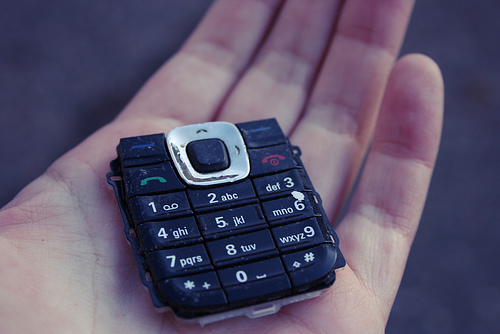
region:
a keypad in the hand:
[107, 102, 349, 323]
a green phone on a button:
[132, 164, 178, 190]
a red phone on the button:
[262, 153, 292, 168]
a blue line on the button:
[125, 133, 157, 151]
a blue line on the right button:
[248, 123, 278, 138]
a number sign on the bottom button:
[301, 249, 317, 264]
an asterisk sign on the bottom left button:
[184, 274, 196, 298]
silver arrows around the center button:
[163, 109, 253, 194]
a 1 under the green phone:
[135, 189, 185, 219]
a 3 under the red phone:
[281, 173, 301, 193]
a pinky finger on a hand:
[333, 52, 468, 279]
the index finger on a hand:
[99, 5, 281, 170]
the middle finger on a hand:
[216, 6, 354, 132]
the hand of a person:
[35, 15, 476, 289]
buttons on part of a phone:
[144, 156, 346, 279]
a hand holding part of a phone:
[70, 54, 487, 292]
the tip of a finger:
[373, 54, 472, 184]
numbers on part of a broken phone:
[145, 123, 368, 310]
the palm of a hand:
[56, 58, 446, 299]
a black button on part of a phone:
[183, 108, 255, 201]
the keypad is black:
[86, 103, 340, 314]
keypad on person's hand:
[61, 3, 402, 330]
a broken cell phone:
[106, 114, 352, 314]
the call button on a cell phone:
[127, 165, 180, 197]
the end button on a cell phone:
[250, 145, 290, 173]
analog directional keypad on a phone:
[163, 121, 251, 189]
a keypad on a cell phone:
[131, 173, 337, 290]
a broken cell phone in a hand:
[0, 0, 452, 329]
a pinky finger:
[336, 52, 451, 303]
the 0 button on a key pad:
[217, 253, 296, 285]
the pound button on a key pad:
[281, 246, 333, 274]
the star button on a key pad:
[176, 266, 220, 307]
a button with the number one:
[132, 198, 189, 215]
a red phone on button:
[249, 151, 291, 180]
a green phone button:
[130, 171, 189, 200]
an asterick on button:
[170, 265, 220, 306]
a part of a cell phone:
[38, 49, 467, 326]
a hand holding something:
[45, 24, 498, 308]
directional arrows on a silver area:
[152, 117, 257, 183]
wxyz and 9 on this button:
[270, 225, 336, 242]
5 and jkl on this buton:
[205, 211, 267, 232]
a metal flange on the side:
[90, 159, 157, 328]